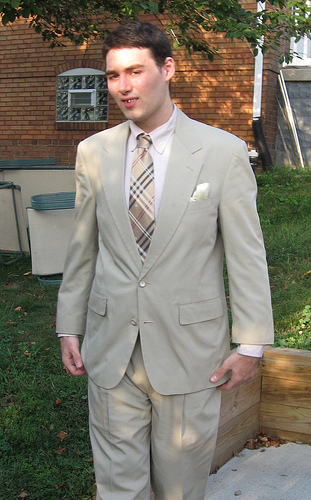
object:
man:
[55, 25, 274, 500]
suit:
[55, 104, 274, 500]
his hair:
[101, 20, 170, 98]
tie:
[127, 133, 155, 266]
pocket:
[187, 199, 214, 211]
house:
[0, 0, 292, 171]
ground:
[206, 441, 311, 499]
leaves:
[246, 430, 285, 450]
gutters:
[252, 0, 274, 174]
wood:
[209, 346, 311, 478]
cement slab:
[207, 443, 311, 498]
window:
[55, 67, 108, 123]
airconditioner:
[68, 89, 94, 108]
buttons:
[139, 280, 146, 288]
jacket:
[55, 103, 274, 395]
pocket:
[179, 296, 224, 326]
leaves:
[56, 428, 68, 443]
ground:
[0, 257, 96, 500]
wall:
[169, 0, 254, 148]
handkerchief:
[190, 183, 209, 203]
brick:
[0, 0, 291, 165]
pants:
[87, 340, 221, 500]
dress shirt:
[125, 102, 178, 223]